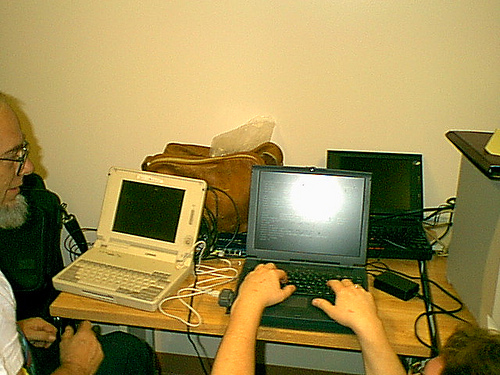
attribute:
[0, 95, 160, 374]
man — older, sitting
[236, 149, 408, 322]
laptop — black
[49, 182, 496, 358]
table — brown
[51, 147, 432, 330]
laptops — old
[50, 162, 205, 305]
laptop — white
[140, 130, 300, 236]
case — brown, leather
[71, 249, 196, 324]
keyboard — white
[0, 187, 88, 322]
bag — black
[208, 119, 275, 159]
plastic — clear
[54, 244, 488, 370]
table — brown, wooden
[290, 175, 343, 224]
glare — large, white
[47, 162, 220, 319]
lap top — white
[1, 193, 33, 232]
beard — white, hairy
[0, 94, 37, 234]
man — older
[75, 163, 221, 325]
laptop — three